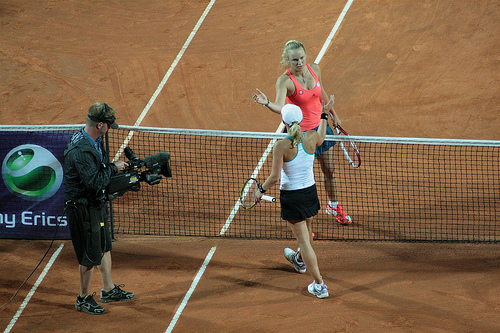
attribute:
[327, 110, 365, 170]
tennis racquet — red, white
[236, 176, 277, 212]
tennis racquet — white, green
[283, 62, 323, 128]
tank top — pink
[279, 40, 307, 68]
hair — blonde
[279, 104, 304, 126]
ball cap — white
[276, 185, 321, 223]
black skirt — short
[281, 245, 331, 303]
tennis shoes — white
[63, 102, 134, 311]
man — filming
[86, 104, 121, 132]
visor — black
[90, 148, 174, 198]
camera — big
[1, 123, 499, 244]
net — used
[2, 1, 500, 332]
ground — brown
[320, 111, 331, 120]
wrist band — black